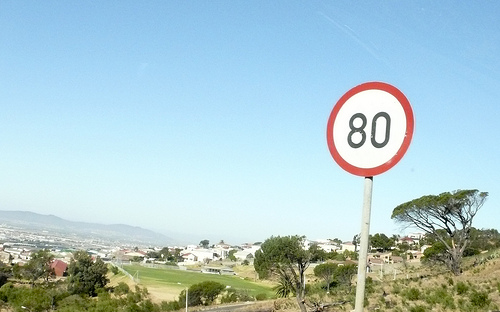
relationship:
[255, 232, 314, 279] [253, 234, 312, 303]
green leaves on tree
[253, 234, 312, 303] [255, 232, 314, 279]
tree has green leaves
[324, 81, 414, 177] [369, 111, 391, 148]
sign has number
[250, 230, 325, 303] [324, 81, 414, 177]
tree next to sign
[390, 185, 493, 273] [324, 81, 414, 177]
tree behind sign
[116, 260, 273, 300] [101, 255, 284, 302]
grass on field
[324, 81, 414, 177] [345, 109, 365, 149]
sign has number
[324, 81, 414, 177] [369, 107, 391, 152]
sign has number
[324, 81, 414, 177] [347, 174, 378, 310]
sign on pole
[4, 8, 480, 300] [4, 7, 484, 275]
photo taken day